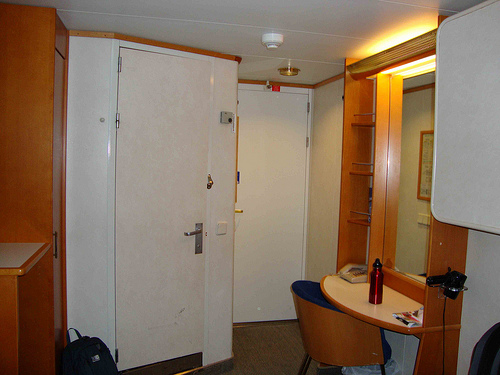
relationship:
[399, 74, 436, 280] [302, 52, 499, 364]
mirror hanging on wall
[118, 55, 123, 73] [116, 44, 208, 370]
hinge on door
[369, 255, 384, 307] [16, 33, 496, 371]
water bottle on bus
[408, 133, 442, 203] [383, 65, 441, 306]
picture on wall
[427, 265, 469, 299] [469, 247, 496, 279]
hairdryer on wall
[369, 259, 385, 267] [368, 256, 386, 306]
top of bottle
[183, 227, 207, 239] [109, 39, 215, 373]
handle on door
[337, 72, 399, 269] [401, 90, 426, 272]
shelf on wall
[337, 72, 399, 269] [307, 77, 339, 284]
shelf on wall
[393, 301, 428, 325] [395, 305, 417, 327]
paper on desk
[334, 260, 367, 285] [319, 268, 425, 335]
phone on desk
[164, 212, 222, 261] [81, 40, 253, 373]
handle on door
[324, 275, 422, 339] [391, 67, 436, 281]
desk in front of mirror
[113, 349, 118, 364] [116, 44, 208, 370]
hinge on door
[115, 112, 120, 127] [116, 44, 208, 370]
hinge on door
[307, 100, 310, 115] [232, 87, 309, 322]
hinge on door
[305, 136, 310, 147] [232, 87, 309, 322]
hinge on door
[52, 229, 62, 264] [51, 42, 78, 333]
handle on door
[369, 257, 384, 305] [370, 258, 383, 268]
water bottle with lid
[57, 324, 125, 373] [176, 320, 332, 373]
backpack on floor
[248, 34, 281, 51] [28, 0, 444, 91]
smoke detector on ceiling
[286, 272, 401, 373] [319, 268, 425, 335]
blue chair under desk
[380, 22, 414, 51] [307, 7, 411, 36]
light on ceiling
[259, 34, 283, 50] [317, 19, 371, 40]
smoke detector on ceiling